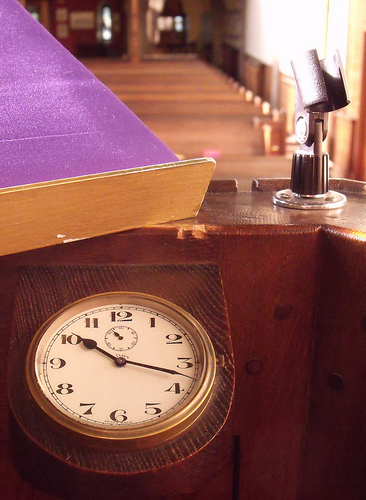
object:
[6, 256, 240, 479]
clock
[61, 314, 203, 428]
10:17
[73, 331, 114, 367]
hand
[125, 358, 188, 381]
hand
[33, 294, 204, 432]
minutes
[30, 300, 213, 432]
hours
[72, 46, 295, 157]
pews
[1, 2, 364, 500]
church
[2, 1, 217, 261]
stand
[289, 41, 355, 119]
microphone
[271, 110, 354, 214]
stand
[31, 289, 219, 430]
face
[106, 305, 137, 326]
12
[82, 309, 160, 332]
11 and 1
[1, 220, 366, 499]
button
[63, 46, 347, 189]
floor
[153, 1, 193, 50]
door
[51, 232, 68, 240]
spot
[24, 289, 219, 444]
rim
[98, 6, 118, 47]
window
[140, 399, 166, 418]
number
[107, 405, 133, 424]
number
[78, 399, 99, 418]
number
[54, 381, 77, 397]
number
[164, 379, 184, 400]
number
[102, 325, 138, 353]
clock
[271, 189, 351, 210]
base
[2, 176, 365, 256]
wood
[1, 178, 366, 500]
desk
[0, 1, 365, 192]
background